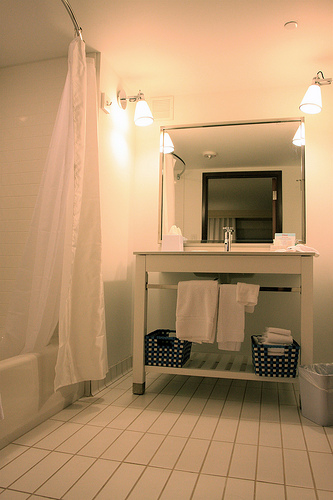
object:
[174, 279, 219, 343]
towel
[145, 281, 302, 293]
rod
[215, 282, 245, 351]
towel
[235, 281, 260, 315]
towel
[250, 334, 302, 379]
basket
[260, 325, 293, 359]
towels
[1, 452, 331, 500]
floor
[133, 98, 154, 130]
sconce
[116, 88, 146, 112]
fixture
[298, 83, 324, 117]
sconce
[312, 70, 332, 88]
fixture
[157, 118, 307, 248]
mirror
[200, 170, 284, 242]
door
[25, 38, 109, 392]
shower curtain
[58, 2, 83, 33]
rod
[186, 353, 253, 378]
slats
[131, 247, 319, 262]
sink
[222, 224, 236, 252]
hardware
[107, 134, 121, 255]
wall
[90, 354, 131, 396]
baseboard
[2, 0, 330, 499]
bathroom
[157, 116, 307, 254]
frame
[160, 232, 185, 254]
tissue box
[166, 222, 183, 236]
tissues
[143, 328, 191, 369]
basket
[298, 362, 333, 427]
trash bin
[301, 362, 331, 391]
plastic bag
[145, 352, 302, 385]
shelf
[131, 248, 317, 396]
sink stand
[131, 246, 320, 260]
countertop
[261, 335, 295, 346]
bath towel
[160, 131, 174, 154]
reflection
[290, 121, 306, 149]
reflection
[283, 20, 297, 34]
smoke alarm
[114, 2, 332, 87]
ceiling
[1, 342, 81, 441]
bathtub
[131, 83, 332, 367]
wall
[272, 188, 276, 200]
door hinge